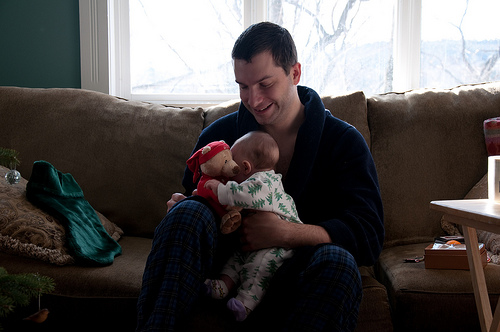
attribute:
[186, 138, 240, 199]
bear — small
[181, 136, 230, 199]
pajamas — red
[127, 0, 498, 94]
window — long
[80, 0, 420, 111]
frame — white, wooden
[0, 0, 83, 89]
wall — green, painted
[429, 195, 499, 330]
tray — wooden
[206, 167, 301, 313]
pajamas — blue, plaid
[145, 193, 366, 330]
pants — blue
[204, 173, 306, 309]
onesie — white, green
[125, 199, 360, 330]
pants — blue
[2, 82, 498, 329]
couch — brown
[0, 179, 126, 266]
pillow — brown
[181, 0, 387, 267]
man — holding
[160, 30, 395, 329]
man — sitting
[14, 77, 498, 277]
couch — brown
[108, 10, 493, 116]
window — white-framed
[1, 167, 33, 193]
ball — silver, hanging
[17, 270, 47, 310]
ornament — hanging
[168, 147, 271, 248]
teddy bear — hugged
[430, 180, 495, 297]
table — brown